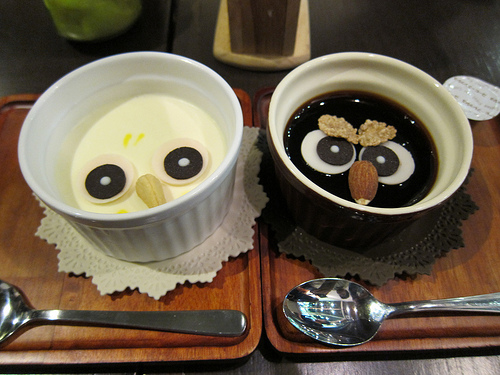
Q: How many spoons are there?
A: Two.